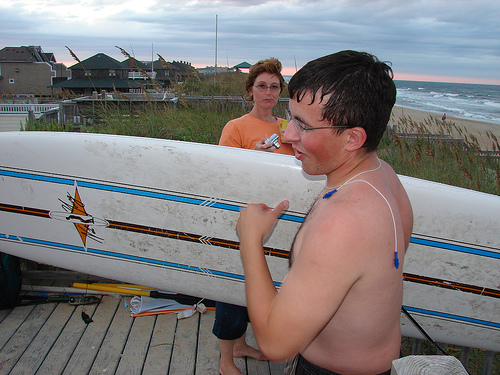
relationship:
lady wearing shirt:
[212, 56, 294, 375] [213, 112, 298, 153]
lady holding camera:
[212, 56, 294, 373] [263, 132, 280, 148]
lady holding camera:
[212, 56, 294, 375] [239, 115, 297, 168]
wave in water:
[425, 102, 462, 111] [399, 79, 499, 117]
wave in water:
[393, 85, 499, 125] [399, 79, 499, 117]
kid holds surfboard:
[232, 47, 416, 375] [1, 125, 498, 355]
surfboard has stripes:
[1, 125, 500, 356] [106, 176, 179, 265]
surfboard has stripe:
[1, 125, 498, 355] [0, 168, 499, 264]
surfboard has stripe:
[1, 125, 498, 355] [0, 163, 499, 262]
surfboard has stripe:
[1, 125, 498, 355] [0, 197, 498, 295]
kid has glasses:
[232, 47, 414, 374] [279, 104, 351, 134]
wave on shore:
[393, 85, 499, 125] [392, 99, 499, 136]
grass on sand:
[17, 70, 255, 146] [386, 104, 500, 154]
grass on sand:
[179, 96, 197, 136] [386, 104, 500, 154]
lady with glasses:
[212, 56, 294, 375] [241, 79, 285, 97]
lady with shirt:
[212, 56, 294, 375] [231, 115, 291, 149]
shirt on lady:
[231, 115, 291, 149] [212, 56, 294, 375]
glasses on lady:
[241, 79, 285, 97] [212, 56, 294, 375]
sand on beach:
[409, 104, 499, 154] [400, 112, 484, 148]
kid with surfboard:
[232, 47, 416, 375] [10, 137, 485, 321]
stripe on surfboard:
[0, 163, 499, 262] [1, 125, 498, 355]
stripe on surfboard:
[0, 197, 498, 295] [1, 125, 498, 355]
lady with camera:
[212, 56, 294, 375] [264, 133, 282, 149]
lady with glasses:
[212, 56, 294, 375] [250, 78, 280, 95]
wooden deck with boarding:
[7, 295, 298, 372] [50, 316, 204, 366]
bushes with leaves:
[92, 94, 207, 139] [103, 87, 179, 125]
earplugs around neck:
[337, 154, 398, 259] [326, 151, 377, 192]